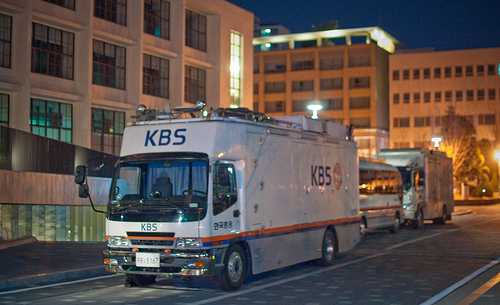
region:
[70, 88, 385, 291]
large vehicle traveling down a street.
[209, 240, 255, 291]
left front tire on a vehicle.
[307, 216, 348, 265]
left rear tire on a vehicle.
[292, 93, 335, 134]
street light on the side of a street.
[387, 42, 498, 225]
tall multi story building near a street.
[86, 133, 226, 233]
front windshield on a truck.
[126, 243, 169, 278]
license plate on a truck.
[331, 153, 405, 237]
bus riding in a caravan.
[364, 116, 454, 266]
A truck at the end of a caravan.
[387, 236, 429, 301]
section of street.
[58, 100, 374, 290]
White kbs truck driving down a street.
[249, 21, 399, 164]
Tall multi story building.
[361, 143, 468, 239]
Truck driving in a caravan down a street.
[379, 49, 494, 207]
Tall building illuminated at night.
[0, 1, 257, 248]
Tall building with lots of windows.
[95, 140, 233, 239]
Front of a large truck.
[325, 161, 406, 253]
A small bus driving between two trucks.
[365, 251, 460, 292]
A section of street near buildings.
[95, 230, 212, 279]
head lights on a trucks.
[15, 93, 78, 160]
A large window on the side of a building.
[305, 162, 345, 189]
logo on side of vehicle.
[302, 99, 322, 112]
street light above vans.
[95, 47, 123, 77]
window on side of building.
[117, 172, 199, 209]
windshield of first van.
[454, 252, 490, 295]
lines painted on street.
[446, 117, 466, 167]
tree on the sidewalk.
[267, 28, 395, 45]
lights on top of building.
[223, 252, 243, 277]
wheel on the van.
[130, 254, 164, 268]
license plate on van.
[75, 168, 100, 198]
side mirror on van.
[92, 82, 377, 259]
the van is white.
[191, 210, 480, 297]
white lines on the street.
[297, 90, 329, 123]
street lights are on.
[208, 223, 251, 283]
the wheel is black.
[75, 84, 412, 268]
the van is parked.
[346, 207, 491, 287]
the concrete is grey.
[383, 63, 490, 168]
the windows are black.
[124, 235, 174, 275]
the license plate is white.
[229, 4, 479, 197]
it is night time.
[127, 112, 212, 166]
the van says KBS.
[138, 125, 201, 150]
Blue lettering on vehicle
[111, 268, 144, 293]
Block under vehicles tire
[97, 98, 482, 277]
Three large white vehicles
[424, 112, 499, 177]
Street lights along the road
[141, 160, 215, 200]
Curtains behind driving compartment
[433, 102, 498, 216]
trees along the road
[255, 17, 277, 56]
Lights on inside building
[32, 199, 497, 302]
Paving stone road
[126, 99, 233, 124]
Spot lights on vehicle roof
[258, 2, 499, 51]
Sky is dark